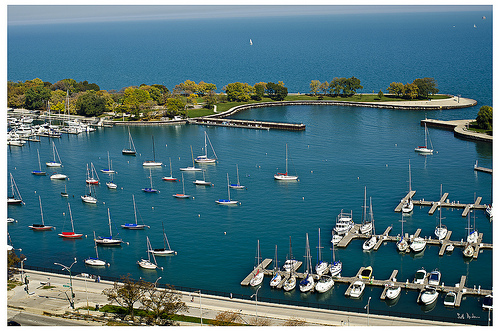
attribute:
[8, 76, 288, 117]
trees — green, yellow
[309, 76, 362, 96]
trees — green, yellow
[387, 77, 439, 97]
trees — green, yellow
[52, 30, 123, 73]
sky — blue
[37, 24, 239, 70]
water — dark blue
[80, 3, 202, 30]
sky — blue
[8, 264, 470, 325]
road — grey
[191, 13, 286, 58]
clouds — white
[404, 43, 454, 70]
clouds — white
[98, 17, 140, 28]
sky — blue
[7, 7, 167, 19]
sky — blue, hazy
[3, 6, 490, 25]
sky — blue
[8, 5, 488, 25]
clouds — white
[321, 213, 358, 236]
boat — red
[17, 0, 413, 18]
sky — blue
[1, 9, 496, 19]
sky — blue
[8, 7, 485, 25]
cloud — white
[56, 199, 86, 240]
boat — red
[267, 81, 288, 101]
tree — green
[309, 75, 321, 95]
tree — green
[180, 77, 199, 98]
tree — green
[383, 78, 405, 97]
tree — green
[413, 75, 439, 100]
tree — green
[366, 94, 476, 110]
beach — light brown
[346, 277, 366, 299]
boat — white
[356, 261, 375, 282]
boat — white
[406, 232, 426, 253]
boat — white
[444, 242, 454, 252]
boat — white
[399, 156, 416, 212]
boat — white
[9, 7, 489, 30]
sky — blue